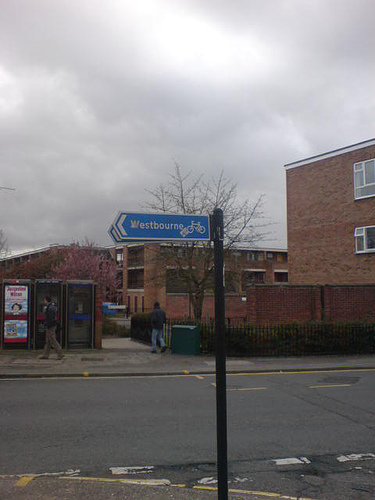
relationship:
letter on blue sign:
[130, 221, 186, 230] [106, 209, 214, 243]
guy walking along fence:
[149, 300, 167, 354] [161, 315, 374, 357]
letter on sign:
[130, 221, 186, 230] [101, 166, 317, 294]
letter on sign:
[130, 217, 200, 233] [110, 207, 210, 240]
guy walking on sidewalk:
[39, 291, 68, 363] [0, 333, 373, 376]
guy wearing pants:
[36, 290, 71, 371] [42, 321, 63, 354]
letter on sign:
[130, 221, 186, 230] [108, 204, 216, 245]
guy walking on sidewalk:
[39, 291, 68, 363] [4, 343, 333, 380]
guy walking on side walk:
[39, 291, 68, 363] [165, 371, 206, 442]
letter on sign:
[130, 221, 186, 230] [106, 208, 213, 247]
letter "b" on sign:
[151, 218, 160, 233] [106, 208, 213, 247]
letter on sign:
[130, 221, 186, 230] [97, 210, 189, 247]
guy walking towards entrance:
[149, 300, 167, 354] [103, 287, 150, 350]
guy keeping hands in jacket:
[149, 300, 167, 354] [147, 307, 168, 330]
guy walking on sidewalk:
[39, 291, 68, 363] [3, 350, 374, 371]